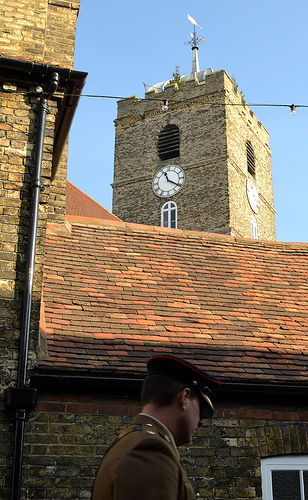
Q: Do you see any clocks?
A: Yes, there is a clock.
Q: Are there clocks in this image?
A: Yes, there is a clock.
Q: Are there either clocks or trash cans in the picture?
A: Yes, there is a clock.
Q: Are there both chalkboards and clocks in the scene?
A: No, there is a clock but no chalkboards.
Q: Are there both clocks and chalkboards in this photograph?
A: No, there is a clock but no chalkboards.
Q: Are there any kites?
A: No, there are no kites.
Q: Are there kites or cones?
A: No, there are no kites or cones.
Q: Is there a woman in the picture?
A: No, there are no women.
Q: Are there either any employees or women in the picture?
A: No, there are no women or employees.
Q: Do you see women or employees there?
A: No, there are no women or employees.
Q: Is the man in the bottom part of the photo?
A: Yes, the man is in the bottom of the image.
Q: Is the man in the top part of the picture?
A: No, the man is in the bottom of the image.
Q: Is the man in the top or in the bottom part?
A: The man is in the bottom of the image.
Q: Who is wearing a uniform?
A: The man is wearing a uniform.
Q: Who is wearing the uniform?
A: The man is wearing a uniform.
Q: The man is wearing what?
A: The man is wearing a uniform.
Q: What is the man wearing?
A: The man is wearing a uniform.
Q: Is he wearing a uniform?
A: Yes, the man is wearing a uniform.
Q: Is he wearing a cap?
A: No, the man is wearing a uniform.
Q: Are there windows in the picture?
A: Yes, there is a window.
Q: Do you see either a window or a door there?
A: Yes, there is a window.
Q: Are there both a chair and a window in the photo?
A: No, there is a window but no chairs.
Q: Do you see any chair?
A: No, there are no chairs.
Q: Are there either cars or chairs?
A: No, there are no chairs or cars.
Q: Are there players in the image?
A: No, there are no players.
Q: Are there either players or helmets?
A: No, there are no players or helmets.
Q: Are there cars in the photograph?
A: No, there are no cars.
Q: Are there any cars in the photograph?
A: No, there are no cars.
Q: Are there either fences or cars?
A: No, there are no cars or fences.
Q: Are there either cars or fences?
A: No, there are no cars or fences.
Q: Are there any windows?
A: Yes, there is a window.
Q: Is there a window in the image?
A: Yes, there is a window.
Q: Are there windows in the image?
A: Yes, there is a window.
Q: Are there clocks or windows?
A: Yes, there is a window.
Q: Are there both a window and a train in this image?
A: No, there is a window but no trains.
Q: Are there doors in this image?
A: No, there are no doors.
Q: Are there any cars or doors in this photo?
A: No, there are no doors or cars.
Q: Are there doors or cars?
A: No, there are no doors or cars.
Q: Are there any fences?
A: No, there are no fences.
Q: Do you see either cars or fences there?
A: No, there are no fences or cars.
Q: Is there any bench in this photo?
A: No, there are no benches.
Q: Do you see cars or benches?
A: No, there are no benches or cars.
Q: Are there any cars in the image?
A: No, there are no cars.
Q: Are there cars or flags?
A: No, there are no cars or flags.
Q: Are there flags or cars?
A: No, there are no cars or flags.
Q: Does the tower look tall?
A: Yes, the tower is tall.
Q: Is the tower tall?
A: Yes, the tower is tall.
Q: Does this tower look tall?
A: Yes, the tower is tall.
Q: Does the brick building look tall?
A: Yes, the tower is tall.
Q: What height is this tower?
A: The tower is tall.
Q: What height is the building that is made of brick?
A: The tower is tall.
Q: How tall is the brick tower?
A: The tower is tall.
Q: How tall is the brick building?
A: The tower is tall.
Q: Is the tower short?
A: No, the tower is tall.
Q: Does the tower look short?
A: No, the tower is tall.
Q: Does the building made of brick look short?
A: No, the tower is tall.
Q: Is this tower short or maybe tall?
A: The tower is tall.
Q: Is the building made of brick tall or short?
A: The tower is tall.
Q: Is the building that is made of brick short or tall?
A: The tower is tall.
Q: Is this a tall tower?
A: Yes, this is a tall tower.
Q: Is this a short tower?
A: No, this is a tall tower.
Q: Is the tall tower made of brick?
A: Yes, the tower is made of brick.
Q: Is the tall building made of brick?
A: Yes, the tower is made of brick.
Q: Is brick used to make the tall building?
A: Yes, the tower is made of brick.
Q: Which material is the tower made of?
A: The tower is made of brick.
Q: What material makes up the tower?
A: The tower is made of brick.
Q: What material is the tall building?
A: The tower is made of brick.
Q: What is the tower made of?
A: The tower is made of brick.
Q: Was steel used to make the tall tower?
A: No, the tower is made of brick.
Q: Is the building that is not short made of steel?
A: No, the tower is made of brick.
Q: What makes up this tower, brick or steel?
A: The tower is made of brick.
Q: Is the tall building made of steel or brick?
A: The tower is made of brick.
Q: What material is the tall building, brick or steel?
A: The tower is made of brick.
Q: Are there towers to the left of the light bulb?
A: Yes, there is a tower to the left of the light bulb.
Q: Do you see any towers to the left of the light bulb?
A: Yes, there is a tower to the left of the light bulb.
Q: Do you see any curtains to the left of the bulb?
A: No, there is a tower to the left of the bulb.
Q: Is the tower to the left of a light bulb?
A: Yes, the tower is to the left of a light bulb.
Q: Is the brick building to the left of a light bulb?
A: Yes, the tower is to the left of a light bulb.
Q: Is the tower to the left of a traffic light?
A: No, the tower is to the left of a light bulb.